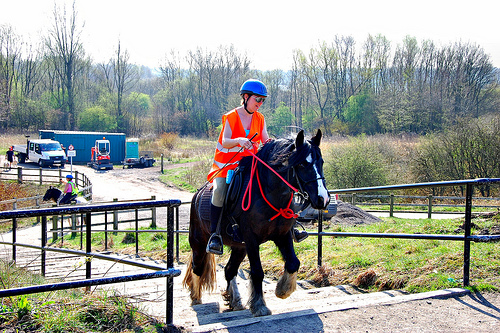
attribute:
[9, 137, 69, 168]
truck — white utility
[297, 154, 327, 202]
patch — white 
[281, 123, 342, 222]
face — horses 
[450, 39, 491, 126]
tree — Brown , no leaves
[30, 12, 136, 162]
tree —  no leaves, Brown 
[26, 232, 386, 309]
stairs — flight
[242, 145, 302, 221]
reigns — red 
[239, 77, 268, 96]
helmet — blue safet riding 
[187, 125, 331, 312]
horse — walking up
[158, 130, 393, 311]
horse — white , black 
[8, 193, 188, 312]
fence — metal  , black  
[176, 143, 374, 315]
horse — show 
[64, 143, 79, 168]
sign — street 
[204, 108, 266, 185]
construction jacket — orange construction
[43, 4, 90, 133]
tree — Brown ,  no leaves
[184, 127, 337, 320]
horse — show 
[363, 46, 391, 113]
tree — no leaves, Brown 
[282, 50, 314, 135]
tree — Brown , no leaves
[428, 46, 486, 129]
tree — tall, no leaves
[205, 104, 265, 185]
vest —  orange safety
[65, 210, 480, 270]
grass — green 